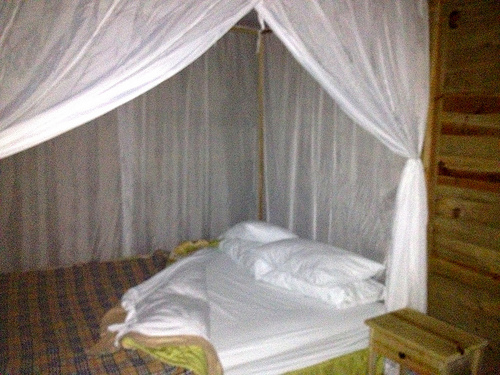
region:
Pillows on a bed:
[233, 205, 367, 320]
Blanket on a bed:
[67, 257, 236, 352]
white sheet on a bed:
[228, 280, 285, 340]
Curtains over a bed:
[41, 38, 153, 85]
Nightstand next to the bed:
[364, 308, 474, 373]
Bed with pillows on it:
[233, 217, 360, 296]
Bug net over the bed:
[74, 139, 241, 194]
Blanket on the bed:
[41, 279, 170, 356]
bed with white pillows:
[256, 233, 374, 310]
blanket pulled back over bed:
[120, 255, 235, 347]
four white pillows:
[214, 208, 381, 323]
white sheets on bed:
[191, 238, 379, 356]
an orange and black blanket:
[4, 264, 206, 374]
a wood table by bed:
[333, 300, 483, 370]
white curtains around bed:
[9, 4, 425, 284]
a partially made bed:
[57, 232, 400, 372]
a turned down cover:
[66, 225, 268, 373]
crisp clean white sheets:
[193, 217, 403, 349]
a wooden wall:
[435, 65, 498, 357]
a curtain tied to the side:
[247, 4, 444, 311]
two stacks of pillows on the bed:
[218, 222, 383, 307]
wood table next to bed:
[364, 307, 474, 373]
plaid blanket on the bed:
[7, 246, 186, 373]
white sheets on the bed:
[133, 252, 380, 366]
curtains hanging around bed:
[3, 2, 425, 309]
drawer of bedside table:
[372, 330, 431, 373]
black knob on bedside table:
[395, 349, 410, 366]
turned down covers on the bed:
[9, 239, 243, 372]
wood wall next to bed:
[430, 42, 498, 373]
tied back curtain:
[262, 9, 429, 327]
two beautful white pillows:
[210, 208, 410, 320]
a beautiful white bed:
[100, 225, 326, 363]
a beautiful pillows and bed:
[102, 218, 396, 372]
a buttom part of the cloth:
[372, 143, 475, 323]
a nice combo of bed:
[38, 216, 369, 363]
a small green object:
[136, 340, 190, 369]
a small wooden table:
[360, 302, 475, 369]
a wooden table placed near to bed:
[354, 303, 484, 372]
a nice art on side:
[420, 15, 499, 179]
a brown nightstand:
[363, 305, 488, 372]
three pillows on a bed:
[218, 224, 387, 304]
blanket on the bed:
[0, 247, 230, 372]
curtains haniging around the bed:
[0, 1, 432, 337]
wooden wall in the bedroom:
[432, 2, 497, 372]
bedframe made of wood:
[280, 349, 397, 372]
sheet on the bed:
[204, 239, 391, 374]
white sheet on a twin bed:
[201, 240, 371, 348]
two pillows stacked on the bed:
[251, 244, 388, 308]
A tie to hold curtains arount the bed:
[251, 8, 268, 60]